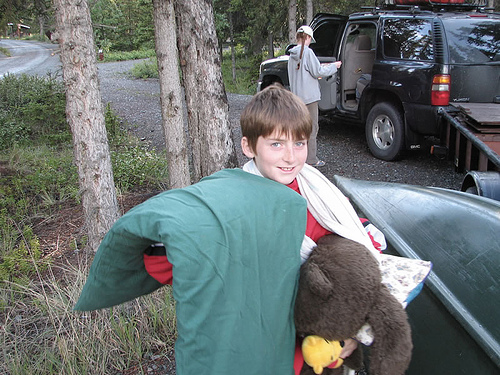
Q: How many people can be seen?
A: Two.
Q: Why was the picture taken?
A: To capture the boy.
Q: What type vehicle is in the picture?
A: A SUV.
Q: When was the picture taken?
A: During the day.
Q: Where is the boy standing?
A: In the grass.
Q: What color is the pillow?
A: Green.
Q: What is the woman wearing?
A: Gray.